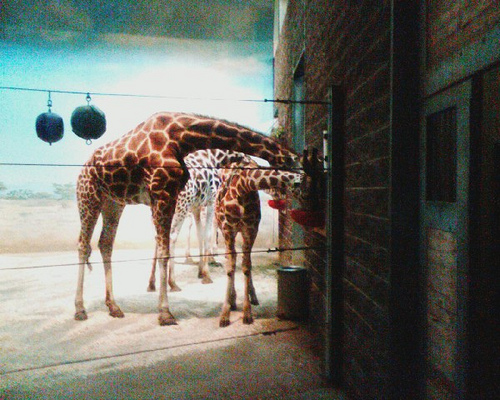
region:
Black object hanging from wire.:
[67, 84, 108, 174]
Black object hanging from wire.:
[33, 96, 84, 178]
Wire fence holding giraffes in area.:
[26, 92, 265, 392]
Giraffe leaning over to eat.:
[259, 161, 333, 214]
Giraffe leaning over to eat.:
[273, 122, 325, 197]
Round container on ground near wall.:
[268, 245, 313, 350]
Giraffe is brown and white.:
[100, 136, 207, 271]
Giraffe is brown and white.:
[220, 162, 303, 259]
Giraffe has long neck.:
[196, 112, 325, 179]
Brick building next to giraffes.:
[258, 47, 496, 347]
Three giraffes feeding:
[10, 63, 416, 360]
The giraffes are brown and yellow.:
[80, 112, 320, 342]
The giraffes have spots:
[111, 139, 172, 202]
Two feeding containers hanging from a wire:
[22, 91, 112, 158]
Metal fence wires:
[2, 94, 309, 364]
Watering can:
[275, 263, 315, 324]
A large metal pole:
[382, 0, 435, 373]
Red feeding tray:
[288, 205, 328, 230]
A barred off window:
[407, 89, 488, 222]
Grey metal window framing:
[405, 197, 477, 237]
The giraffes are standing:
[53, 98, 327, 338]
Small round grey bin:
[262, 255, 333, 338]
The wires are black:
[17, 82, 349, 376]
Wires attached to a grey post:
[272, 81, 367, 387]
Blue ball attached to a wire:
[27, 97, 122, 145]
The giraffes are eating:
[62, 132, 339, 324]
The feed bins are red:
[264, 183, 339, 245]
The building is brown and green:
[264, 67, 479, 389]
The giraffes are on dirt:
[48, 106, 305, 355]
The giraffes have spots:
[69, 97, 291, 329]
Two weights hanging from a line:
[34, 76, 136, 151]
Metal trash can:
[273, 270, 301, 320]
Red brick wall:
[337, 22, 389, 340]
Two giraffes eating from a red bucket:
[67, 86, 353, 317]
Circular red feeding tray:
[290, 198, 330, 227]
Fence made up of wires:
[6, 87, 349, 361]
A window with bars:
[420, 85, 466, 220]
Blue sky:
[12, 38, 265, 117]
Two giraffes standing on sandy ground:
[64, 125, 285, 327]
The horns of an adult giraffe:
[289, 145, 318, 165]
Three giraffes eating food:
[47, 92, 414, 359]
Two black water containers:
[29, 102, 116, 152]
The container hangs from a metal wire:
[71, 87, 121, 145]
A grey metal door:
[402, 94, 480, 383]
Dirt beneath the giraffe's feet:
[70, 339, 175, 388]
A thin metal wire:
[10, 343, 255, 377]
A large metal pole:
[306, 66, 346, 378]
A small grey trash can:
[269, 259, 319, 329]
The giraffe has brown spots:
[90, 148, 175, 210]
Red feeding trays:
[285, 198, 327, 225]